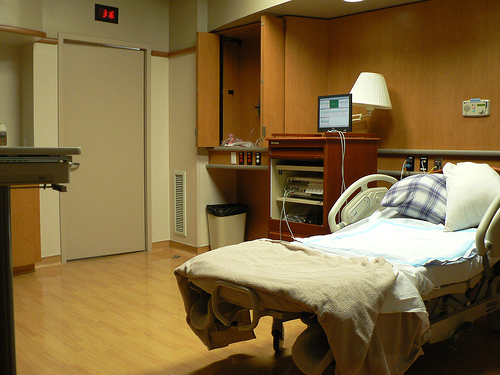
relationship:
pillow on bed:
[383, 164, 440, 229] [172, 160, 497, 371]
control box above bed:
[460, 95, 490, 117] [172, 160, 497, 371]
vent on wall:
[164, 163, 204, 248] [118, 63, 196, 244]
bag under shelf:
[205, 200, 246, 250] [206, 140, 265, 171]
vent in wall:
[169, 171, 187, 240] [173, 62, 191, 168]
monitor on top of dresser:
[316, 95, 350, 137] [274, 125, 334, 208]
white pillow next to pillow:
[444, 161, 496, 231] [380, 174, 449, 224]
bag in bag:
[204, 200, 249, 217] [205, 200, 246, 250]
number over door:
[102, 12, 115, 19] [62, 35, 148, 255]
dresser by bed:
[267, 131, 381, 242] [172, 160, 497, 371]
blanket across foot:
[171, 236, 433, 373] [151, 240, 363, 323]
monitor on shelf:
[316, 95, 350, 137] [263, 131, 373, 146]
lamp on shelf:
[354, 70, 389, 118] [273, 104, 363, 168]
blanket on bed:
[171, 236, 433, 373] [172, 172, 499, 374]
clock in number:
[94, 1, 121, 25] [102, 12, 115, 19]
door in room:
[62, 35, 148, 255] [0, 2, 497, 374]